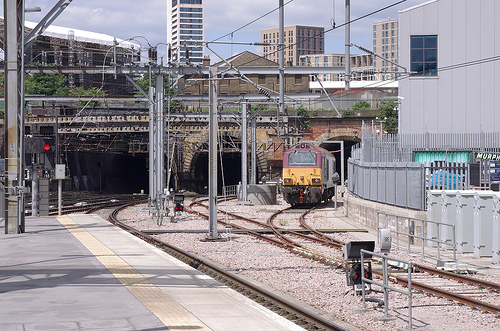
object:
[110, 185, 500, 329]
tracks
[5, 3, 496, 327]
railroad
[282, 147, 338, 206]
engine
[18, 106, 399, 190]
bridge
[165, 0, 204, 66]
building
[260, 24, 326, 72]
building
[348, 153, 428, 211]
fence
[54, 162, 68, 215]
cannister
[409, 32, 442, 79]
window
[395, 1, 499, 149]
building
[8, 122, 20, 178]
rust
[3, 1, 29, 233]
pole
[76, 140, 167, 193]
tunnels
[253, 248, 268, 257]
gravel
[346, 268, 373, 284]
lights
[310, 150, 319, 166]
wipers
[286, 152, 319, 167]
window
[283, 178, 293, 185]
headlights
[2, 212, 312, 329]
walkway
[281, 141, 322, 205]
front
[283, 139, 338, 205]
train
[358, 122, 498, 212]
fencing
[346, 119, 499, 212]
metal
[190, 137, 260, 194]
tunnel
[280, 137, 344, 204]
trains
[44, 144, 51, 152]
light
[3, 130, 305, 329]
station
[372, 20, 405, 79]
buildings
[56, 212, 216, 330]
line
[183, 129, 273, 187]
archway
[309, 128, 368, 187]
archway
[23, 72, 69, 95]
trees